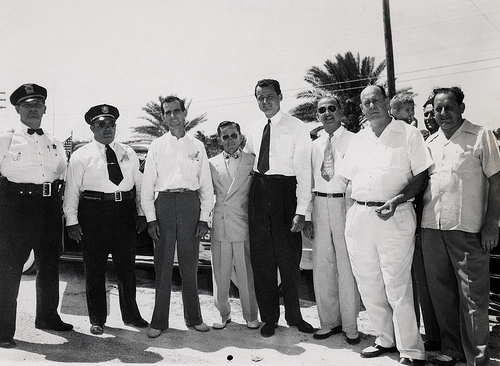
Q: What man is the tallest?
A: The fifth from the left.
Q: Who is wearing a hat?
A: The two men on the far left.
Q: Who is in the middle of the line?
A: Short man with sunglasses.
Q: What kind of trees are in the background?
A: Palm trees.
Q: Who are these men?
A: Town authorities and businessmen.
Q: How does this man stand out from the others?
A: Short stature.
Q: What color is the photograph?
A: Black and white.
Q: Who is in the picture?
A: A group of men.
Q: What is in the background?
A: Palm trees.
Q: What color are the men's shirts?
A: White.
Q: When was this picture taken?
A: Daytime.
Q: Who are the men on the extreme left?
A: Policemen.